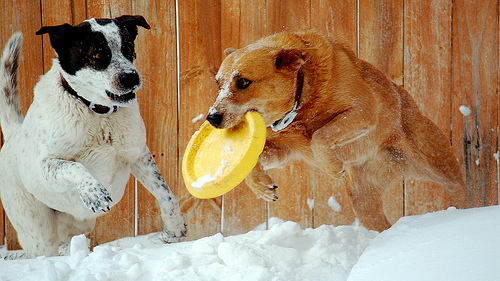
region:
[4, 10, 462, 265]
Two dogs playing in the snow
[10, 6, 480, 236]
Two dogs playing frisbee in the snow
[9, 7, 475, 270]
A white dog and a brown dog playing frisbee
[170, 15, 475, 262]
A brown dog jumps with a frisbee in his mouth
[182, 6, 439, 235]
A brown dog with a yellow brisbee in his mouth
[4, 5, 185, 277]
White and black dog with his tail in the air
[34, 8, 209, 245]
White and black dog with his paw in the air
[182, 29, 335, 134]
Brown dog with a yellow frisbee in his mouth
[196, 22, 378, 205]
Brown dog with his front paws tuck under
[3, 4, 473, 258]
Brown dog running from white dog with frisbee in mouth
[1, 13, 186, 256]
this is a black and white dog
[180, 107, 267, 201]
this is a frissby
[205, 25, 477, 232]
this is a brown dog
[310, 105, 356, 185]
this is his left arm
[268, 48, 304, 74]
thats the dog's ear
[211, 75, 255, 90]
these are his eyes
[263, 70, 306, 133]
this is his collar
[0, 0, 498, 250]
thats a wood fence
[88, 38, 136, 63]
these are the white dogs eyes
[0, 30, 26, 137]
this is his tail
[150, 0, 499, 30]
wooden fence used for boundaries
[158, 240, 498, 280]
snow on ground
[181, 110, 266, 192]
yellow disc used as dog toy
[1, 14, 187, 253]
white and black dog standing on hind legs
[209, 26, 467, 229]
dog with yellow fur standing on hind legs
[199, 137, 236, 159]
hollowed out space in disc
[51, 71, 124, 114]
collar on dog to show ownership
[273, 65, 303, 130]
collar on dog to use for leash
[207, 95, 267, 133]
dog mout to grab frisbees and eat food and drink water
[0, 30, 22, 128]
tail of dog for wagging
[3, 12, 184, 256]
white dog with black eyes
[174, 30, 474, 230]
brown dog with frisbee in mouth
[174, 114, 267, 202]
yellow frisbee is round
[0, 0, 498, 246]
wooden fence behind dog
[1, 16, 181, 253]
dog is in front of wooden fence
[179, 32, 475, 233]
dog is in front of wooden fence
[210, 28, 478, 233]
brown dog has black nose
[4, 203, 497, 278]
white snow under doog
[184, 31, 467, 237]
brown dog playing on top of snow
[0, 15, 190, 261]
white dog playing on top of snow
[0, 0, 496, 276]
Two dogs are next to each other.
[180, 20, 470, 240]
One dog is yellow.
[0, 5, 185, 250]
One dog has white and black fur.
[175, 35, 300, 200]
A frisbee is in the dog's mouth.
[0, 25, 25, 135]
The dog's tail is white with black spots.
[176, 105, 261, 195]
The frisbee is yellow.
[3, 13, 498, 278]
The dogs are playing in the snow.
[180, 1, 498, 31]
The fence is made out of wood.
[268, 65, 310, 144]
The dog is wearing a collar.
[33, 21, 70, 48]
The dog has a black ear.